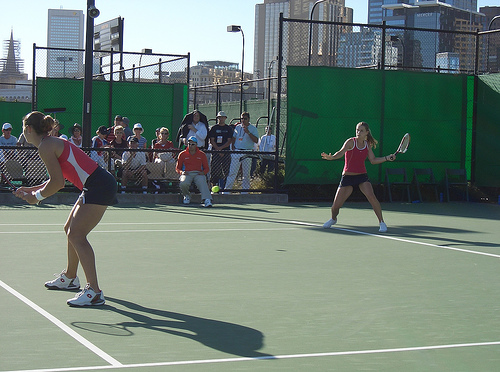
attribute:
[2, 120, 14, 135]
cap — white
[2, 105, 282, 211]
audience — baseball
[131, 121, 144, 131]
hat — white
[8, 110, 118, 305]
tennis player — bent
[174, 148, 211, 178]
pull-over — orange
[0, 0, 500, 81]
sky — blue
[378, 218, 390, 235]
shoe — white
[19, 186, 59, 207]
wristband — white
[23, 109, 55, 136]
hair — brown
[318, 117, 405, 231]
girl — playing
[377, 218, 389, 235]
shoe — athletic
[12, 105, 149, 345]
player — tennis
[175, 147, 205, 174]
shirt — red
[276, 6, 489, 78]
fence — chain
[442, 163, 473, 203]
chair — empty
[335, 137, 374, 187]
uniform — red, black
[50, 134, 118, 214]
uniform — black, red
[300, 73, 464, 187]
mesh — green